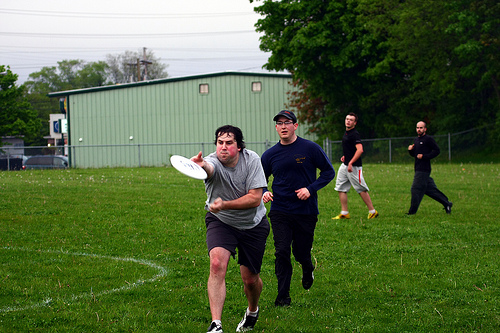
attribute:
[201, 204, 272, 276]
shorts — dark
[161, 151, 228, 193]
frisbee — white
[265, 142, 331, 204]
top — blue, yellow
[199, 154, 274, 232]
shirt — grey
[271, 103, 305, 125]
cap. — dark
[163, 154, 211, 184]
disc — flying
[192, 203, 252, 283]
pants — dark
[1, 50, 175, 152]
trees — tall, green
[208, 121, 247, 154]
hair — black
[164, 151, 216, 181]
disc — flying, white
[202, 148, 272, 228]
shirt — grey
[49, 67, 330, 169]
building — green